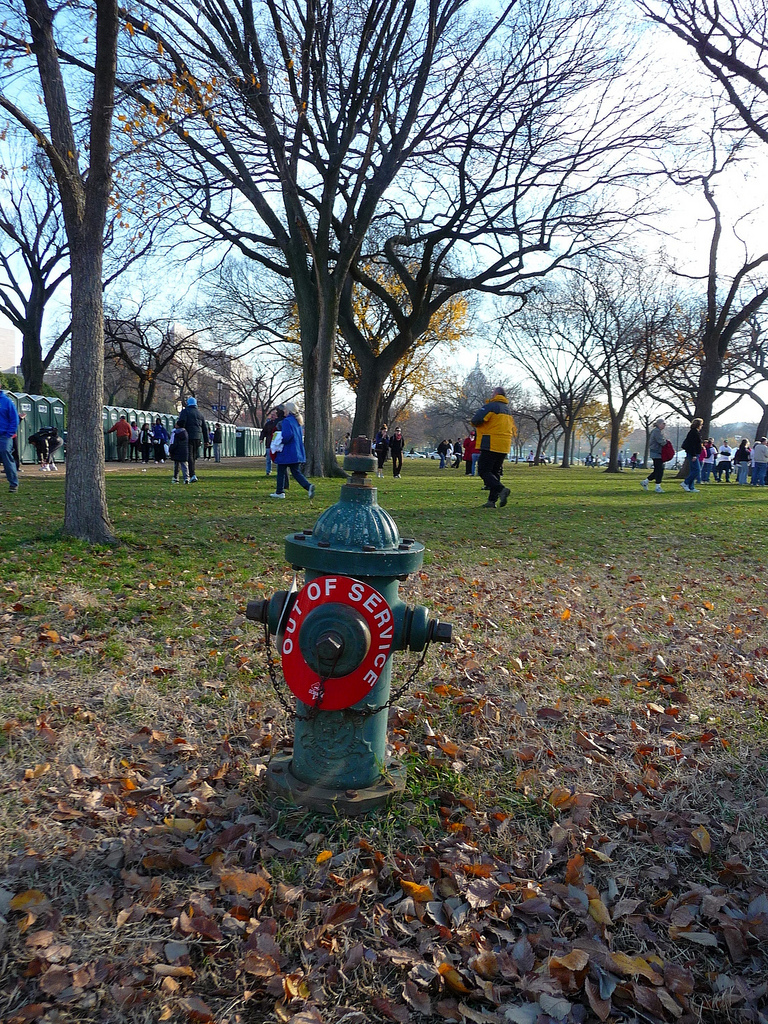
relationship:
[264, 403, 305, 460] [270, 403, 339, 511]
coat on woman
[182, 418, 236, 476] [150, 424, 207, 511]
adult with child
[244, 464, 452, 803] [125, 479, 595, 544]
fire hydrant with grass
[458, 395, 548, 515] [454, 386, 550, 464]
man with jacket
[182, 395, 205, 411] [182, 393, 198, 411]
hat on head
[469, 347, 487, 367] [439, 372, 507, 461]
steeple on building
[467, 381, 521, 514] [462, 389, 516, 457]
man wearing yellow jacket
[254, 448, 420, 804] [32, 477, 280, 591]
fire hydrant in grass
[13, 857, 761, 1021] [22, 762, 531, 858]
leaves in grass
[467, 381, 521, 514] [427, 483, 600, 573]
man walking through grass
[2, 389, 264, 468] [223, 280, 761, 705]
port-a-potties in park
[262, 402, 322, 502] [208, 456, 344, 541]
woman walking through grass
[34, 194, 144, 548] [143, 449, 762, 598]
tree in park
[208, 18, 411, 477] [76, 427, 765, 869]
tree in park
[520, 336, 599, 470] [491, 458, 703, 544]
tree in grass field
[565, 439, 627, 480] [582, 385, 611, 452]
people surrounding tree